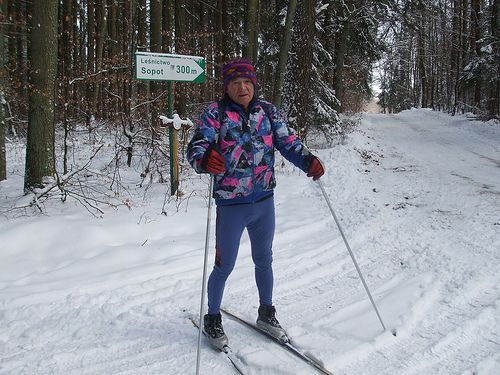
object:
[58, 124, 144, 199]
patch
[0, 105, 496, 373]
snow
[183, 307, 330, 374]
skis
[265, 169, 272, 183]
pink patch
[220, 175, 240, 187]
pink patch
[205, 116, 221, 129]
pink patch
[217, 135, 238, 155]
patch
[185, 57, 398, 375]
elderly skiier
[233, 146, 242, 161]
pink patch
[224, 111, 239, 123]
pink patch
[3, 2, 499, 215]
forest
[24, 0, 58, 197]
trees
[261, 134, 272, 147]
patch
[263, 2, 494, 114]
trees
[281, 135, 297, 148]
patch